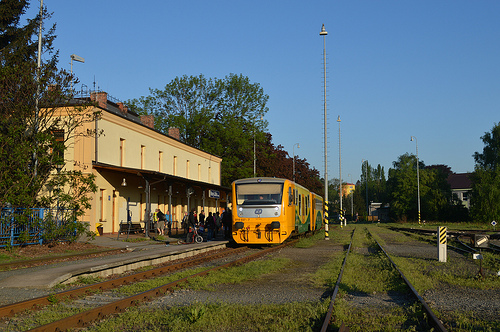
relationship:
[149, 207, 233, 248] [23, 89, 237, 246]
people at station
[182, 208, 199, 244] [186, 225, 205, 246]
person holding tricycle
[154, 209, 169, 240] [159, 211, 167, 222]
man with backpack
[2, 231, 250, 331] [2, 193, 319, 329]
grass on tracks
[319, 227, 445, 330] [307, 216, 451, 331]
grass on tracks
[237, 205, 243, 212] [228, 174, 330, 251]
headlights on train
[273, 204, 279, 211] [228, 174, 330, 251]
headlights on train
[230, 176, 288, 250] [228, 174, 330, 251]
front of train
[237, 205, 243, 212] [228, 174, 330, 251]
headlights of train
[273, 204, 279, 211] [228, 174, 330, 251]
headlights of train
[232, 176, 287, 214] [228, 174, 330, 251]
glass on train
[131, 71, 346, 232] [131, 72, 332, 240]
group of trees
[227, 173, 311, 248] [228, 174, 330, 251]
car of train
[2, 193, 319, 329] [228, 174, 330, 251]
tracks of train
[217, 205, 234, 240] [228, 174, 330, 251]
passenger boarding train